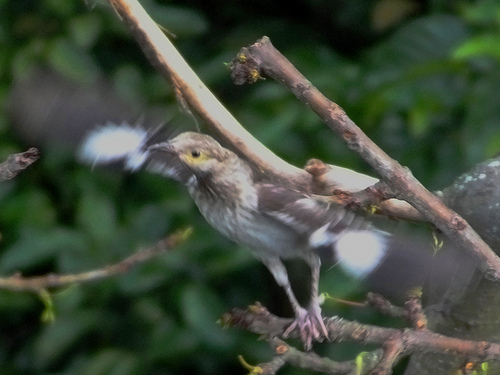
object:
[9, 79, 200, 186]
wing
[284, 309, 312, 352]
feet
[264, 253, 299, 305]
legs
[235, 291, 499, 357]
branch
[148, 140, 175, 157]
beak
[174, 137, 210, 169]
face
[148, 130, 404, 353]
bird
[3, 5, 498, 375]
vegetation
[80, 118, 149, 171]
spot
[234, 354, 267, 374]
blossom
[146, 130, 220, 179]
head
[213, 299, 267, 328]
tip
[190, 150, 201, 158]
eye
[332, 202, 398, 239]
tail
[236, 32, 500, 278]
branch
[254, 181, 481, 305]
wing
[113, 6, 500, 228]
branches